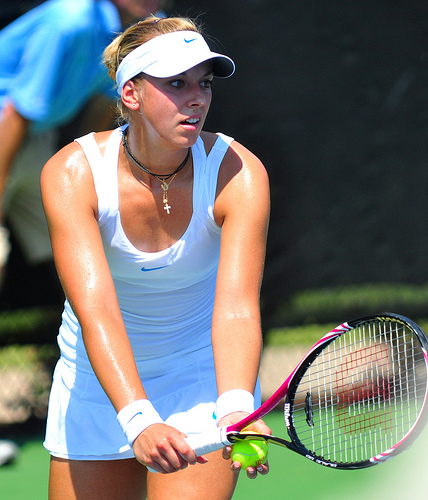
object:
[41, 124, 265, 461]
dress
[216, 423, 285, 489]
ball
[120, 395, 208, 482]
hand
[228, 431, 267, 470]
ball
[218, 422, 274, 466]
ball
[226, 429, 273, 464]
ball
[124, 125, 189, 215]
necklace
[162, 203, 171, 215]
cross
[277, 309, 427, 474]
head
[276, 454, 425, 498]
floor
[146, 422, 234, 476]
handle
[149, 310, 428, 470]
racket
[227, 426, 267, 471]
ball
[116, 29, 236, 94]
hat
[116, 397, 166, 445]
sweatbands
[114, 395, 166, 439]
wrists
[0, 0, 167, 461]
person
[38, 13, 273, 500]
tennis player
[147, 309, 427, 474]
tennis racket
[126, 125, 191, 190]
neck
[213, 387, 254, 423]
sweatband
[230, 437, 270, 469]
tennis ball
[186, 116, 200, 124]
teeth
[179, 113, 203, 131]
mouth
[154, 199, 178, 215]
cross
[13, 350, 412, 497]
court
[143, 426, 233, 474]
tape